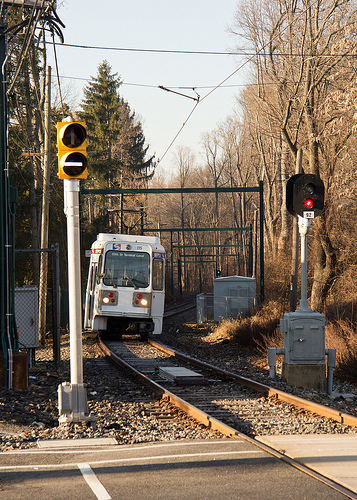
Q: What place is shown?
A: It is a railroad.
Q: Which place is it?
A: It is a railroad.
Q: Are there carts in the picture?
A: No, there are no carts.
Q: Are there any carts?
A: No, there are no carts.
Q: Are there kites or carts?
A: No, there are no carts or kites.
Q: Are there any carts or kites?
A: No, there are no carts or kites.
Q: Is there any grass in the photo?
A: Yes, there is grass.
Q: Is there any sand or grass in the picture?
A: Yes, there is grass.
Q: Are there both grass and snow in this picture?
A: No, there is grass but no snow.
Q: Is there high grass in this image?
A: Yes, there is high grass.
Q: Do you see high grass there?
A: Yes, there is high grass.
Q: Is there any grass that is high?
A: Yes, there is grass that is high.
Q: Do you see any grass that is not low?
A: Yes, there is high grass.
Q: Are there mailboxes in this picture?
A: No, there are no mailboxes.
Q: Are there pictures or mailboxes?
A: No, there are no mailboxes or pictures.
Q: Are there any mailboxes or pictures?
A: No, there are no mailboxes or pictures.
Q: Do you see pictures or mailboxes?
A: No, there are no mailboxes or pictures.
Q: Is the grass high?
A: Yes, the grass is high.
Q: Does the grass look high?
A: Yes, the grass is high.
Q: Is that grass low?
A: No, the grass is high.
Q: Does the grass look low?
A: No, the grass is high.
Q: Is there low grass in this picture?
A: No, there is grass but it is high.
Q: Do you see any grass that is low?
A: No, there is grass but it is high.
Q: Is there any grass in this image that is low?
A: No, there is grass but it is high.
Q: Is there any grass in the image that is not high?
A: No, there is grass but it is high.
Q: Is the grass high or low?
A: The grass is high.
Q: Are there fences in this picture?
A: Yes, there is a fence.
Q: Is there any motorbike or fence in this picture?
A: Yes, there is a fence.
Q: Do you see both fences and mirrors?
A: No, there is a fence but no mirrors.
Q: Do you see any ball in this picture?
A: No, there are no balls.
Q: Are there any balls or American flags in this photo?
A: No, there are no balls or American flags.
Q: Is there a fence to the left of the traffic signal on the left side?
A: Yes, there is a fence to the left of the traffic signal.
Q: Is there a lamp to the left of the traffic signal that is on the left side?
A: No, there is a fence to the left of the signal light.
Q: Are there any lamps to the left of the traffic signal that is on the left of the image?
A: No, there is a fence to the left of the signal light.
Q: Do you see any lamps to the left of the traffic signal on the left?
A: No, there is a fence to the left of the signal light.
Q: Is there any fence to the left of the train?
A: Yes, there is a fence to the left of the train.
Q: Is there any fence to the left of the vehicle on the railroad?
A: Yes, there is a fence to the left of the train.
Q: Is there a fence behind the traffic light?
A: Yes, there is a fence behind the traffic light.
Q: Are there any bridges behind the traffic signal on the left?
A: No, there is a fence behind the signal light.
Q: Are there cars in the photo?
A: No, there are no cars.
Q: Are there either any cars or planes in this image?
A: No, there are no cars or planes.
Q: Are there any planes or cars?
A: No, there are no cars or planes.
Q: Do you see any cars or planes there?
A: No, there are no cars or planes.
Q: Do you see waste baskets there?
A: No, there are no waste baskets.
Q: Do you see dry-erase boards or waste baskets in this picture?
A: No, there are no waste baskets or dry-erase boards.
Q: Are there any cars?
A: No, there are no cars.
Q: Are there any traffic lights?
A: Yes, there is a traffic light.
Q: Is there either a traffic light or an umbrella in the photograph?
A: Yes, there is a traffic light.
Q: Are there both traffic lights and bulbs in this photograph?
A: No, there is a traffic light but no light bulbs.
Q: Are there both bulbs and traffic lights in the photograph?
A: No, there is a traffic light but no light bulbs.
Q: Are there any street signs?
A: No, there are no street signs.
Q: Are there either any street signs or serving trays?
A: No, there are no street signs or serving trays.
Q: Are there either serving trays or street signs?
A: No, there are no street signs or serving trays.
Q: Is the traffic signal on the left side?
A: Yes, the traffic signal is on the left of the image.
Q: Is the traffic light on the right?
A: No, the traffic light is on the left of the image.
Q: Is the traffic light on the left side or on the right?
A: The traffic light is on the left of the image.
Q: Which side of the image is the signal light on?
A: The signal light is on the left of the image.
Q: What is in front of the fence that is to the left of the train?
A: The traffic light is in front of the fence.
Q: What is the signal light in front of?
A: The signal light is in front of the fence.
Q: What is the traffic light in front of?
A: The signal light is in front of the fence.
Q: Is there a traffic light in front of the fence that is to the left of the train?
A: Yes, there is a traffic light in front of the fence.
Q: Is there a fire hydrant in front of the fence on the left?
A: No, there is a traffic light in front of the fence.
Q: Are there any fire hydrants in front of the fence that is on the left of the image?
A: No, there is a traffic light in front of the fence.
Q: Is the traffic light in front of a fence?
A: Yes, the traffic light is in front of a fence.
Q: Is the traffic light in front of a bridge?
A: No, the traffic light is in front of a fence.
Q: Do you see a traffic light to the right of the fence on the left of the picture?
A: Yes, there is a traffic light to the right of the fence.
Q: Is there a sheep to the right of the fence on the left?
A: No, there is a traffic light to the right of the fence.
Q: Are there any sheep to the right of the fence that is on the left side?
A: No, there is a traffic light to the right of the fence.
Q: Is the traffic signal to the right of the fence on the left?
A: Yes, the traffic signal is to the right of the fence.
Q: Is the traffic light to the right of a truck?
A: No, the traffic light is to the right of the fence.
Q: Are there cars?
A: No, there are no cars.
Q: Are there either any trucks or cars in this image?
A: No, there are no cars or trucks.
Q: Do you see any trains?
A: Yes, there is a train.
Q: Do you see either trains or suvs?
A: Yes, there is a train.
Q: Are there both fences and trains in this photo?
A: Yes, there are both a train and a fence.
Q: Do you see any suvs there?
A: No, there are no suvs.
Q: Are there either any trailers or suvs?
A: No, there are no suvs or trailers.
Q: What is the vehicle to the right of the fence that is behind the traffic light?
A: The vehicle is a train.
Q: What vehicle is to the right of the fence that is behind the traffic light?
A: The vehicle is a train.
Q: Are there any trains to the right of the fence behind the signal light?
A: Yes, there is a train to the right of the fence.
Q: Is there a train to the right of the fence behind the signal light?
A: Yes, there is a train to the right of the fence.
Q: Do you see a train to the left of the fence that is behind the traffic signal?
A: No, the train is to the right of the fence.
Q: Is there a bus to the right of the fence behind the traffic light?
A: No, there is a train to the right of the fence.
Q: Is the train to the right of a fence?
A: Yes, the train is to the right of a fence.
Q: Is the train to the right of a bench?
A: No, the train is to the right of a fence.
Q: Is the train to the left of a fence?
A: No, the train is to the right of a fence.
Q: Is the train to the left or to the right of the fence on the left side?
A: The train is to the right of the fence.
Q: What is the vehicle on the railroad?
A: The vehicle is a train.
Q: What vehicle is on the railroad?
A: The vehicle is a train.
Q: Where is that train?
A: The train is on the railroad.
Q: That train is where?
A: The train is on the railroad.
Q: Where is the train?
A: The train is on the railroad.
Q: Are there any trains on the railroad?
A: Yes, there is a train on the railroad.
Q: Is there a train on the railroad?
A: Yes, there is a train on the railroad.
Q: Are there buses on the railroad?
A: No, there is a train on the railroad.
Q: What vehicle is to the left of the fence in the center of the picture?
A: The vehicle is a train.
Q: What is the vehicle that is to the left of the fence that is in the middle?
A: The vehicle is a train.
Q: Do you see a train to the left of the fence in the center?
A: Yes, there is a train to the left of the fence.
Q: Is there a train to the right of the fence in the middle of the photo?
A: No, the train is to the left of the fence.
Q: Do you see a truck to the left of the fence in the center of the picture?
A: No, there is a train to the left of the fence.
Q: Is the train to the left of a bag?
A: No, the train is to the left of the fence.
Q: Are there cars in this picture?
A: No, there are no cars.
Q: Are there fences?
A: Yes, there is a fence.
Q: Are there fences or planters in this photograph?
A: Yes, there is a fence.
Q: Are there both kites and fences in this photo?
A: No, there is a fence but no kites.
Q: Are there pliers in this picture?
A: No, there are no pliers.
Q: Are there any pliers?
A: No, there are no pliers.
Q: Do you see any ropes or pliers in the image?
A: No, there are no pliers or ropes.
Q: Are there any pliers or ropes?
A: No, there are no pliers or ropes.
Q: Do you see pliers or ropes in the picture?
A: No, there are no pliers or ropes.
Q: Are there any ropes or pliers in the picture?
A: No, there are no pliers or ropes.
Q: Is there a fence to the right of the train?
A: Yes, there is a fence to the right of the train.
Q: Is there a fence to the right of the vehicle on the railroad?
A: Yes, there is a fence to the right of the train.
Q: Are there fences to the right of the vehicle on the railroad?
A: Yes, there is a fence to the right of the train.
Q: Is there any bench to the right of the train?
A: No, there is a fence to the right of the train.